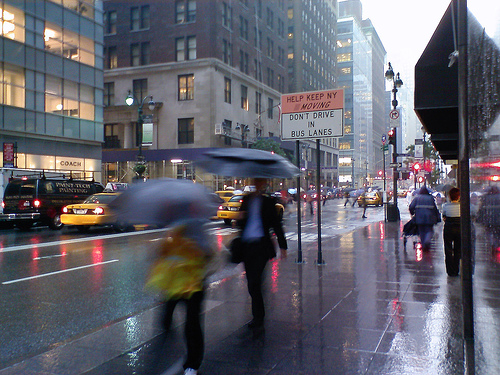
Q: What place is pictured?
A: It is a road.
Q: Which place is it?
A: It is a road.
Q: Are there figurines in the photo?
A: No, there are no figurines.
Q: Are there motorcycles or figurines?
A: No, there are no figurines or motorcycles.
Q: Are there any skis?
A: No, there are no skis.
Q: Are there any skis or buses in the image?
A: No, there are no skis or buses.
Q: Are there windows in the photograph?
A: Yes, there is a window.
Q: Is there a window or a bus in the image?
A: Yes, there is a window.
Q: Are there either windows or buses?
A: Yes, there is a window.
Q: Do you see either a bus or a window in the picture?
A: Yes, there is a window.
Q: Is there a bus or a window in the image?
A: Yes, there is a window.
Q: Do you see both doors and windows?
A: No, there is a window but no doors.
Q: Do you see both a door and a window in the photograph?
A: No, there is a window but no doors.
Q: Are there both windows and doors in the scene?
A: No, there is a window but no doors.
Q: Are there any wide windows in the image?
A: Yes, there is a wide window.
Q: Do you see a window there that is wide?
A: Yes, there is a window that is wide.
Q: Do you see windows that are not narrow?
A: Yes, there is a wide window.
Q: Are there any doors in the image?
A: No, there are no doors.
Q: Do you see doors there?
A: No, there are no doors.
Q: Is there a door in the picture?
A: No, there are no doors.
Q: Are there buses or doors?
A: No, there are no doors or buses.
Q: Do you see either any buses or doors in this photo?
A: No, there are no doors or buses.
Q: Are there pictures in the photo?
A: No, there are no pictures.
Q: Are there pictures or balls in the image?
A: No, there are no pictures or balls.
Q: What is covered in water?
A: The glass is covered in water.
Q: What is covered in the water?
A: The glass is covered in water.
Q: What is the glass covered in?
A: The glass is covered in water.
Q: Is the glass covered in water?
A: Yes, the glass is covered in water.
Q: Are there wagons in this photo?
A: No, there are no wagons.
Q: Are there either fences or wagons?
A: No, there are no wagons or fences.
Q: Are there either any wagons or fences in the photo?
A: No, there are no wagons or fences.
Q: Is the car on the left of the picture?
A: Yes, the car is on the left of the image.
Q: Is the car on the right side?
A: No, the car is on the left of the image.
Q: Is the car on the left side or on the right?
A: The car is on the left of the image.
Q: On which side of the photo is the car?
A: The car is on the left of the image.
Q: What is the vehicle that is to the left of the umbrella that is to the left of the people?
A: The vehicle is a car.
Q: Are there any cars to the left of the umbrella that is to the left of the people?
A: Yes, there is a car to the left of the umbrella.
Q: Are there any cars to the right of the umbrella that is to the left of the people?
A: No, the car is to the left of the umbrella.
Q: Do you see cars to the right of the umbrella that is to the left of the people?
A: No, the car is to the left of the umbrella.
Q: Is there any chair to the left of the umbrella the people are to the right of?
A: No, there is a car to the left of the umbrella.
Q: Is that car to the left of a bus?
A: No, the car is to the left of the umbrella.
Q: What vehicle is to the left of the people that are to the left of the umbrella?
A: The vehicle is a car.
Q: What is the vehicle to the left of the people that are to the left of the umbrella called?
A: The vehicle is a car.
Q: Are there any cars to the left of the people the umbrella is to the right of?
A: Yes, there is a car to the left of the people.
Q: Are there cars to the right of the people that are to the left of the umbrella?
A: No, the car is to the left of the people.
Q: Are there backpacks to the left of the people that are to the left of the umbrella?
A: No, there is a car to the left of the people.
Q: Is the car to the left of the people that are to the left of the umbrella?
A: Yes, the car is to the left of the people.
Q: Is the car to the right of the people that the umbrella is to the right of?
A: No, the car is to the left of the people.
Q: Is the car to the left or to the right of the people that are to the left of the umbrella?
A: The car is to the left of the people.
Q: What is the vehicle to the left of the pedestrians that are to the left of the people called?
A: The vehicle is a car.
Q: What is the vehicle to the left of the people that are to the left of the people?
A: The vehicle is a car.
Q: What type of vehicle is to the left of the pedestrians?
A: The vehicle is a car.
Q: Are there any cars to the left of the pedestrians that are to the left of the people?
A: Yes, there is a car to the left of the pedestrians.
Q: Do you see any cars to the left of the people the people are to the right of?
A: Yes, there is a car to the left of the pedestrians.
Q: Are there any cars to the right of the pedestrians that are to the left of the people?
A: No, the car is to the left of the pedestrians.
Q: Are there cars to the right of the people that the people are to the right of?
A: No, the car is to the left of the pedestrians.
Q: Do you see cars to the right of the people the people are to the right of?
A: No, the car is to the left of the pedestrians.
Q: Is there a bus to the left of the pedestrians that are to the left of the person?
A: No, there is a car to the left of the pedestrians.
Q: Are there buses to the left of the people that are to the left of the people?
A: No, there is a car to the left of the pedestrians.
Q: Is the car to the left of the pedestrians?
A: Yes, the car is to the left of the pedestrians.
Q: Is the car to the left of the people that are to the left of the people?
A: Yes, the car is to the left of the pedestrians.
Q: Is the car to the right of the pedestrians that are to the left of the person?
A: No, the car is to the left of the pedestrians.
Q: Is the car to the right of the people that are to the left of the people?
A: No, the car is to the left of the pedestrians.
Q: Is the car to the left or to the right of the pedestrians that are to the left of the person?
A: The car is to the left of the pedestrians.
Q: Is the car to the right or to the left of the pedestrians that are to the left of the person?
A: The car is to the left of the pedestrians.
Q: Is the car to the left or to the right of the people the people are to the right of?
A: The car is to the left of the pedestrians.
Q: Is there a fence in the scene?
A: No, there are no fences.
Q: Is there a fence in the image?
A: No, there are no fences.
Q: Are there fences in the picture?
A: No, there are no fences.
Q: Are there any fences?
A: No, there are no fences.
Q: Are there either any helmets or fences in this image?
A: No, there are no fences or helmets.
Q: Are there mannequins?
A: No, there are no mannequins.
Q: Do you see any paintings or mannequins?
A: No, there are no mannequins or paintings.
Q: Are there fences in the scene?
A: No, there are no fences.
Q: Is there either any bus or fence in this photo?
A: No, there are no fences or buses.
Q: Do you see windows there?
A: Yes, there is a window.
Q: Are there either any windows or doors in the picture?
A: Yes, there is a window.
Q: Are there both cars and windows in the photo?
A: Yes, there are both a window and a car.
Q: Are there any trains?
A: No, there are no trains.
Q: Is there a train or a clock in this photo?
A: No, there are no trains or clocks.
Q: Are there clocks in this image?
A: No, there are no clocks.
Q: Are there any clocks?
A: No, there are no clocks.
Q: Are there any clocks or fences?
A: No, there are no clocks or fences.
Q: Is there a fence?
A: No, there are no fences.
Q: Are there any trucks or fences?
A: No, there are no fences or trucks.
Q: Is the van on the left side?
A: Yes, the van is on the left of the image.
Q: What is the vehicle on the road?
A: The vehicle is a van.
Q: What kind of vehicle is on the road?
A: The vehicle is a van.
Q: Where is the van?
A: The van is on the road.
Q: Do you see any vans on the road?
A: Yes, there is a van on the road.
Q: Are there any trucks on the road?
A: No, there is a van on the road.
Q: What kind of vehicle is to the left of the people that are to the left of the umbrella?
A: The vehicle is a van.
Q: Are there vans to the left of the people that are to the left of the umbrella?
A: Yes, there is a van to the left of the people.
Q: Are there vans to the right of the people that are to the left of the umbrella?
A: No, the van is to the left of the people.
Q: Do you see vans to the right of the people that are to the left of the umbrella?
A: No, the van is to the left of the people.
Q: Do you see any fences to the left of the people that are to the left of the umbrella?
A: No, there is a van to the left of the people.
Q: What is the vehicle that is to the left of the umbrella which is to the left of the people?
A: The vehicle is a van.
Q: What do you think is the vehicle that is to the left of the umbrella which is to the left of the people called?
A: The vehicle is a van.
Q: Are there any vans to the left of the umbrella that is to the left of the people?
A: Yes, there is a van to the left of the umbrella.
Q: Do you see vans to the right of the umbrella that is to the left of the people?
A: No, the van is to the left of the umbrella.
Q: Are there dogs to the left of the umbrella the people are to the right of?
A: No, there is a van to the left of the umbrella.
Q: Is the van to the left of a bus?
A: No, the van is to the left of an umbrella.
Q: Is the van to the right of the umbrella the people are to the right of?
A: No, the van is to the left of the umbrella.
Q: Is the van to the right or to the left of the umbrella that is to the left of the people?
A: The van is to the left of the umbrella.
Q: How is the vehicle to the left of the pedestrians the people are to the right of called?
A: The vehicle is a van.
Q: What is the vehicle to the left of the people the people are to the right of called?
A: The vehicle is a van.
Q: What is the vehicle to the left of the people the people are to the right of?
A: The vehicle is a van.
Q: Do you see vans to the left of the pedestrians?
A: Yes, there is a van to the left of the pedestrians.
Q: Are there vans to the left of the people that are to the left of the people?
A: Yes, there is a van to the left of the pedestrians.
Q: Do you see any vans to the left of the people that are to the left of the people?
A: Yes, there is a van to the left of the pedestrians.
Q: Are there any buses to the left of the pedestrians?
A: No, there is a van to the left of the pedestrians.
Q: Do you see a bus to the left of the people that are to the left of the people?
A: No, there is a van to the left of the pedestrians.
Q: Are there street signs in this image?
A: Yes, there is a street sign.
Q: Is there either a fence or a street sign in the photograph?
A: Yes, there is a street sign.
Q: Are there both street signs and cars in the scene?
A: Yes, there are both a street sign and a car.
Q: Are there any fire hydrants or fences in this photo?
A: No, there are no fences or fire hydrants.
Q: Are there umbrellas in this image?
A: Yes, there is an umbrella.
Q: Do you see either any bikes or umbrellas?
A: Yes, there is an umbrella.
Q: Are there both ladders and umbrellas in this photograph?
A: No, there is an umbrella but no ladders.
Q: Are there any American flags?
A: No, there are no American flags.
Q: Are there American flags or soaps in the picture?
A: No, there are no American flags or soaps.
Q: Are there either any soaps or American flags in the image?
A: No, there are no American flags or soaps.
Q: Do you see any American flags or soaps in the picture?
A: No, there are no American flags or soaps.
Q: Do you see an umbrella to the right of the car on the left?
A: Yes, there is an umbrella to the right of the car.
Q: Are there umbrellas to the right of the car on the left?
A: Yes, there is an umbrella to the right of the car.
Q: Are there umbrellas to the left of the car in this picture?
A: No, the umbrella is to the right of the car.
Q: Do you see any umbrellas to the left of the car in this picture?
A: No, the umbrella is to the right of the car.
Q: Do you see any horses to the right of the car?
A: No, there is an umbrella to the right of the car.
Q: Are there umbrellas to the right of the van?
A: Yes, there is an umbrella to the right of the van.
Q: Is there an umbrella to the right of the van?
A: Yes, there is an umbrella to the right of the van.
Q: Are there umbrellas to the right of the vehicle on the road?
A: Yes, there is an umbrella to the right of the van.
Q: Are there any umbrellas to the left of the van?
A: No, the umbrella is to the right of the van.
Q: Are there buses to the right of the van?
A: No, there is an umbrella to the right of the van.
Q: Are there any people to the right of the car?
A: Yes, there are people to the right of the car.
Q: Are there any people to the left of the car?
A: No, the people are to the right of the car.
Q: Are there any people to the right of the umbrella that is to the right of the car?
A: Yes, there are people to the right of the umbrella.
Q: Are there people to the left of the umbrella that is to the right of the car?
A: No, the people are to the right of the umbrella.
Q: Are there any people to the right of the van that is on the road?
A: Yes, there are people to the right of the van.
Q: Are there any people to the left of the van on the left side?
A: No, the people are to the right of the van.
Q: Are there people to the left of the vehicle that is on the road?
A: No, the people are to the right of the van.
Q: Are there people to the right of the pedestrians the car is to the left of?
A: Yes, there are people to the right of the pedestrians.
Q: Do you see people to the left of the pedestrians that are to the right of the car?
A: No, the people are to the right of the pedestrians.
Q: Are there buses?
A: No, there are no buses.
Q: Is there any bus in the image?
A: No, there are no buses.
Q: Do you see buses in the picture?
A: No, there are no buses.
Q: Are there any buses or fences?
A: No, there are no buses or fences.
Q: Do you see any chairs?
A: No, there are no chairs.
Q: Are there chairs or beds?
A: No, there are no chairs or beds.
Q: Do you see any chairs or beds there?
A: No, there are no chairs or beds.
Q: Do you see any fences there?
A: No, there are no fences.